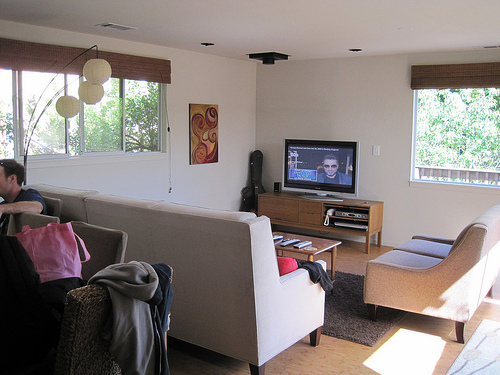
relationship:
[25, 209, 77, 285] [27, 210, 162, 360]
pink bag on chair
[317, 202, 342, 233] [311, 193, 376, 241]
telephone on shelf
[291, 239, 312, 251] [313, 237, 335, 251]
remote on coffee table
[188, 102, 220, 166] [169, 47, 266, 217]
painting on wall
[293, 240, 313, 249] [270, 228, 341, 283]
remote on coffee table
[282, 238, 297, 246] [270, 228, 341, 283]
remote control on coffee table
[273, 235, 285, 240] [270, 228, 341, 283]
remote control on coffee table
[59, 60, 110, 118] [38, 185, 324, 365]
light above couch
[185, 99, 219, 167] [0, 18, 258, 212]
painting above wall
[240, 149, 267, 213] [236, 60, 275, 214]
case in corner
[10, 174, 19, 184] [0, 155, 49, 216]
ear of a man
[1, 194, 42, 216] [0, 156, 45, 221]
arm of a man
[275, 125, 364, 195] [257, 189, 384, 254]
television on console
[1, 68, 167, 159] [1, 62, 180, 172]
row of windows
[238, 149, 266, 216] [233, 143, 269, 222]
case in corner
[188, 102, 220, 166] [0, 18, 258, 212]
painting on wall